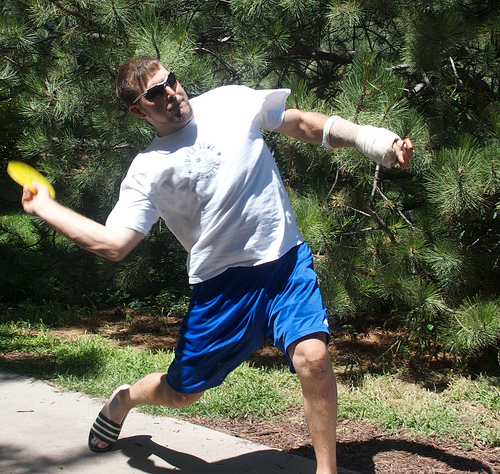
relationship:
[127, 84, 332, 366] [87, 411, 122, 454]
man wearing shoe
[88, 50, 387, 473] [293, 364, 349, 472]
man has bare leg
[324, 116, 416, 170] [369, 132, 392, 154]
arm has cast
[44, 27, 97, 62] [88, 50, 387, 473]
tree behind man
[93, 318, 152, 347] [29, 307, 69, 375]
trail has bark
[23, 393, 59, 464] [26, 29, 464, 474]
path in park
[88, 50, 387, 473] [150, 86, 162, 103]
man wearing sunglasses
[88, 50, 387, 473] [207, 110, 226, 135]
man wearing shirt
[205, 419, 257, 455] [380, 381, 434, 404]
floor on ground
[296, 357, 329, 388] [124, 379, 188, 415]
knee on leg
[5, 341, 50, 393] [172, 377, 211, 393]
edge of short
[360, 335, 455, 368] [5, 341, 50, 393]
shade on edge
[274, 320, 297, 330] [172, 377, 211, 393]
part of short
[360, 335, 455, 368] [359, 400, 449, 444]
shade on ground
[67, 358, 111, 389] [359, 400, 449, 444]
grass on ground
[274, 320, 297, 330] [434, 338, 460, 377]
part of grass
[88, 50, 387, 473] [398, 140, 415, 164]
man has right hand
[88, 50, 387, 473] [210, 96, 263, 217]
man has shirt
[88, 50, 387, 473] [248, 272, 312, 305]
man wearing shorts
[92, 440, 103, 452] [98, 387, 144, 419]
shoe on right foot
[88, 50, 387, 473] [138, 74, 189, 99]
man has sunglasses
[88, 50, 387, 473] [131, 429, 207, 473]
man has shadow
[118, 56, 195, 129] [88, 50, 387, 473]
head on man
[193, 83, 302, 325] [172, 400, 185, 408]
man left knee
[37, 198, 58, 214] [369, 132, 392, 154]
wrist has cast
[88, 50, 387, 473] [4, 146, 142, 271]
man throwing frissbe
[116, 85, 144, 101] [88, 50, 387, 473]
hair on man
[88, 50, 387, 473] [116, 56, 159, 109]
man has hair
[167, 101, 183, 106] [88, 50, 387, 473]
moustache on man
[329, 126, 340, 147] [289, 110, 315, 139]
cast on arm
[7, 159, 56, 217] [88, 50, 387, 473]
cast of man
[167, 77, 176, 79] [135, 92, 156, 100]
sunglasses are being worn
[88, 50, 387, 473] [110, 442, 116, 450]
man wearing flipflop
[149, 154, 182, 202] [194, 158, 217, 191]
shirt has emblem